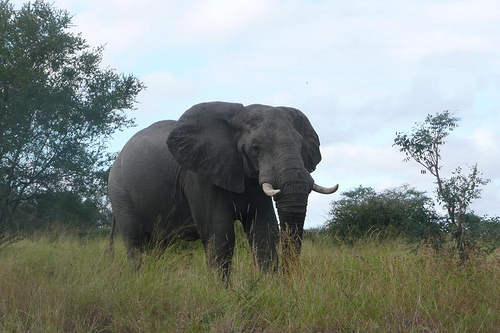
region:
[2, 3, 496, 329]
A safari scene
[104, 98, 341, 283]
This is an elephant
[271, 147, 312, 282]
The elephant's trunk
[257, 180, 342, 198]
The elephant has tusks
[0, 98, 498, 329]
The elephant is standing in grass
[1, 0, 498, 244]
Trees are growing near the elephant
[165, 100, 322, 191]
The elephant has large ears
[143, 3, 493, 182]
The sky is cloudy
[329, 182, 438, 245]
A bush is growing in the grass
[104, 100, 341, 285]
The elephant's skin is gray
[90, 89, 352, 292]
this is an African elephant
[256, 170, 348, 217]
the elephant has tusks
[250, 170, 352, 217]
the elephant's tusks are white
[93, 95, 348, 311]
the elephant is standing in tall grass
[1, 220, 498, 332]
the tall grass is dry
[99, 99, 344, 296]
the elephant is dark grey in color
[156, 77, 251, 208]
this is the elephants ear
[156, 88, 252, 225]
the elephants ear is very large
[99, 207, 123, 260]
this is the elephant's tail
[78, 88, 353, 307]
the elephant has wrinkly skin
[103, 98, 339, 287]
A large, gray elephant.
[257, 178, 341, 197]
Sharp, white elephant tusks.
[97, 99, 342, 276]
An elephant walking in the grass.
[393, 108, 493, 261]
A small tree in the grass.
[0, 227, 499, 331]
Tall grass browned from the sun.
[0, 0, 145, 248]
A large tree filled with leaves.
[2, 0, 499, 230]
A clear, blue sky with fluffy clouds.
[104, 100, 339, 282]
An elephant with large floppy ears.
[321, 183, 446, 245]
A green bush in the background.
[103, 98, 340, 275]
An elephant standing in the grass.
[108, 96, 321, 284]
big gray elephant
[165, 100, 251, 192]
big gray right ear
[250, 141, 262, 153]
small black right eye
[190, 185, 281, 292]
two big front legs of gray elephant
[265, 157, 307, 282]
large gray trunk of elephant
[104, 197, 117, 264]
little thin tail of elephant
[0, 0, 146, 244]
big tree in the left side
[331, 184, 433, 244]
little green bush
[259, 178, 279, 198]
little white right fang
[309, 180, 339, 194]
little white left fang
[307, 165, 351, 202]
a tusk on an elephant.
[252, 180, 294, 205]
the right tusk of an elephant.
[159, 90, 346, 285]
A giant elephant head.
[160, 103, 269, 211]
the right ear of an elephant.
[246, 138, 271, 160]
the right eye of an elephant.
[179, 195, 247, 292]
the right leg of an elephant.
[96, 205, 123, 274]
an elephant's tail.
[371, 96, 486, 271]
a plant with leaves.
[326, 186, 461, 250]
a bush in a field.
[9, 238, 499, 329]
a field full of green grass.